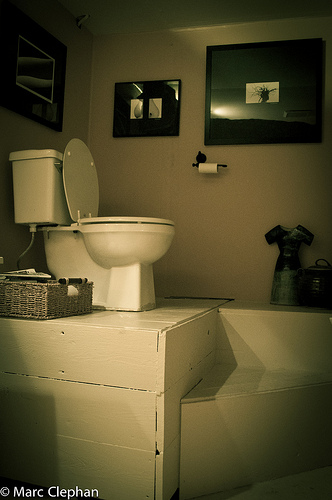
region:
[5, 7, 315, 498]
a toilet in a bathroom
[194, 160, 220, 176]
a white paper towel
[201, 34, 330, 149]
a picture on a wall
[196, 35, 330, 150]
a picture with black frame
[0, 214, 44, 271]
pike linking on a wall an a tank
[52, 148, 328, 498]
stairs to go up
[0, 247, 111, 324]
a basket next a toilet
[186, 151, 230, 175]
the handle of paper towel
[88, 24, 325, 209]
pictures on a wall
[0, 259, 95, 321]
a magazine on a basket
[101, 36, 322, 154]
pictures on the wall of the room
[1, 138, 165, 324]
white porcelain toilet in the bathroom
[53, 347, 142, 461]
white wood wall of the riser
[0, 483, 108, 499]
name and copyright of the photographer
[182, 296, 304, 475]
white wood steps of the riser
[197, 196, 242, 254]
white wall of the bathroom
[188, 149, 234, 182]
a black metal toilet paper holder attached to the wall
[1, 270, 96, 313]
a tan wicker basket on the floor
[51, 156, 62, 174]
shiny grey metal lever of the toilet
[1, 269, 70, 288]
newspapers in the wicker basket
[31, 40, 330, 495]
the scene is in a bathroom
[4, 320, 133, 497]
the drawer is white in colour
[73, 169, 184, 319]
the toilet is white in colour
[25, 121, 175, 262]
the seat is open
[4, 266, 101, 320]
the basket is made of reeds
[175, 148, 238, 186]
a tissue roll on the wall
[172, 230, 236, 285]
the wall is white in colour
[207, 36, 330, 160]
a television on the wall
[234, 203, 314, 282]
a model dress on the wall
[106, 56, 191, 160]
a black portrait on the wall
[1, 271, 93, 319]
the basket next to the toilet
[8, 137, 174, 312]
the white toilet bowl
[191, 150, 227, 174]
the toilet paper holder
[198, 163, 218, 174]
the toilet paper roll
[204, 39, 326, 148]
the picture frame on the wall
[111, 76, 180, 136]
the picture frame on the wall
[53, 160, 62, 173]
the handle on the toilet bowl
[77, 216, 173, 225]
the toilet seat on the toilet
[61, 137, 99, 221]
the toilet seat cover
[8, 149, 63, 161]
the cover for the tank on the toilet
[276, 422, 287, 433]
part of a stair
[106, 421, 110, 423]
part of a drawer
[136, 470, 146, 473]
part of the floor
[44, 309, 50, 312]
part of a basket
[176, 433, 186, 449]
part of a wall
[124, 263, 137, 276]
part of a toilet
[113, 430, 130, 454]
side of a wall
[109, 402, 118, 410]
edge of a stair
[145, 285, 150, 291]
edge of a toilet